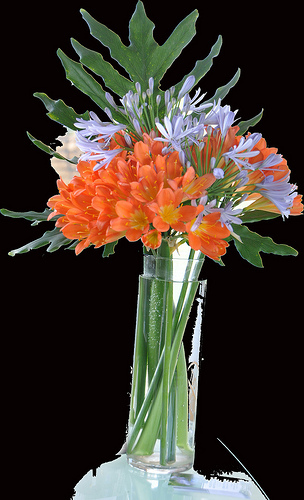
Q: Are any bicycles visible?
A: No, there are no bicycles.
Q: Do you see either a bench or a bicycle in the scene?
A: No, there are no bicycles or benches.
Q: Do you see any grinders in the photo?
A: No, there are no grinders.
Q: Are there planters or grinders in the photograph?
A: No, there are no grinders or planters.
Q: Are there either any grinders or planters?
A: No, there are no grinders or planters.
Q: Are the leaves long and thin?
A: Yes, the leaves are long and thin.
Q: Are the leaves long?
A: Yes, the leaves are long.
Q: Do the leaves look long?
A: Yes, the leaves are long.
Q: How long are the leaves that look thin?
A: The leaves are long.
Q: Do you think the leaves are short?
A: No, the leaves are long.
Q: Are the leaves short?
A: No, the leaves are long.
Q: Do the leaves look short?
A: No, the leaves are long.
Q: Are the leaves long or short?
A: The leaves are long.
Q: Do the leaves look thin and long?
A: Yes, the leaves are thin and long.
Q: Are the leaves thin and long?
A: Yes, the leaves are thin and long.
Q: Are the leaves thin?
A: Yes, the leaves are thin.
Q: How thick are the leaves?
A: The leaves are thin.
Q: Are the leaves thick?
A: No, the leaves are thin.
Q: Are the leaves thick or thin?
A: The leaves are thin.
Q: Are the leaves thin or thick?
A: The leaves are thin.